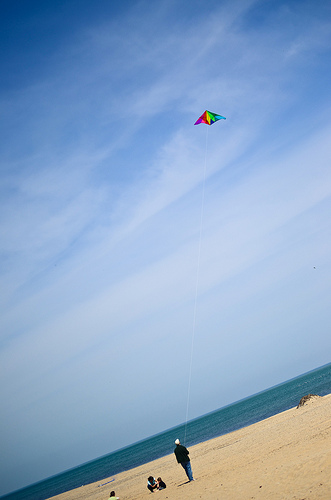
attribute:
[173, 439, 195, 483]
man — on the beach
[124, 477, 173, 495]
woman — on the sand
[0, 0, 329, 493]
sky — in the sky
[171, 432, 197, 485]
man — on the sand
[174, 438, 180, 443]
white hat — on the sand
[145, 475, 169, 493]
children — in the sand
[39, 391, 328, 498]
sand — on the beach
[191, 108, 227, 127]
kite — on the beach, in the air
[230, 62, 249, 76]
ground — has a patch of sand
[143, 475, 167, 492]
children — on the beach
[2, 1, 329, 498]
blue sky — clear blue.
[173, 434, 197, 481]
man — wearing jacket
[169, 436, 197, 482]
man — was wearing a white hat, wearing a white shirt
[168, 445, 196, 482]
man — was wearing a white hat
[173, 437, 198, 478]
man — on the beach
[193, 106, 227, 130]
kite — rainbow colored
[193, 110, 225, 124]
kite — in the sky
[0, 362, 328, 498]
water — on the sand, blue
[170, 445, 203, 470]
shirt — black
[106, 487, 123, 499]
person — on the beach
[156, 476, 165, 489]
child — on the beach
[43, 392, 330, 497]
beach — on the sand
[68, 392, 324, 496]
sand — in the sky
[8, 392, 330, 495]
sand — brown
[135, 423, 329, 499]
sand — patch, on beach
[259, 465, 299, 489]
sand — patch 